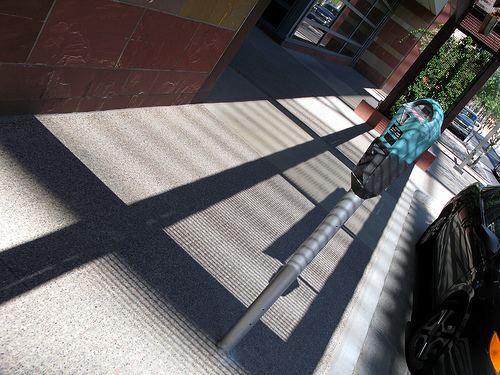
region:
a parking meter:
[350, 90, 450, 200]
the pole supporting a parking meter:
[217, 189, 362, 357]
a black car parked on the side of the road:
[411, 166, 497, 373]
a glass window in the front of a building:
[281, 0, 409, 60]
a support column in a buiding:
[440, 55, 497, 133]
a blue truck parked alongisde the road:
[451, 102, 481, 139]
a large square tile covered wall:
[0, 1, 259, 115]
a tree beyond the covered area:
[402, 43, 483, 119]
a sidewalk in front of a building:
[1, 102, 382, 373]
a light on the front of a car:
[486, 329, 498, 370]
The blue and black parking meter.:
[355, 84, 440, 209]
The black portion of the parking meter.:
[354, 143, 400, 196]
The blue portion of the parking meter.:
[379, 97, 446, 152]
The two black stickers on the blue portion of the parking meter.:
[389, 122, 407, 144]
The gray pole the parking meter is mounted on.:
[229, 187, 365, 334]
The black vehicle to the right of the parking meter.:
[412, 154, 497, 374]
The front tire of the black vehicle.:
[405, 301, 468, 357]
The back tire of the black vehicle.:
[414, 200, 449, 245]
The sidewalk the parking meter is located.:
[43, 137, 371, 361]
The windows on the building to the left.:
[286, 2, 408, 59]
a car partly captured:
[405, 168, 499, 373]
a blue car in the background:
[448, 92, 483, 146]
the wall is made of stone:
[1, 2, 253, 104]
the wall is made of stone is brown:
[30, 0, 141, 66]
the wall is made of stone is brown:
[122, 14, 233, 69]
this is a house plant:
[383, 22, 498, 126]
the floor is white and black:
[3, 84, 498, 371]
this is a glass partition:
[281, 1, 388, 56]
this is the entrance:
[203, 0, 435, 98]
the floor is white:
[40, 95, 300, 203]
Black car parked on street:
[414, 171, 499, 373]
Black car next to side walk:
[404, 181, 499, 367]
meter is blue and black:
[344, 73, 443, 216]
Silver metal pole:
[222, 177, 357, 369]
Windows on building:
[287, 5, 389, 72]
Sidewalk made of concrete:
[3, 71, 388, 366]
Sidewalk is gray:
[6, 55, 393, 372]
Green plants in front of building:
[375, 33, 492, 153]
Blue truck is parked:
[447, 98, 477, 143]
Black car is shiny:
[404, 181, 497, 371]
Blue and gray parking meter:
[350, 61, 448, 238]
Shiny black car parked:
[406, 181, 498, 369]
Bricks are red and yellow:
[2, 2, 256, 110]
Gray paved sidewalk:
[1, 79, 416, 374]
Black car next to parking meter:
[214, 96, 499, 374]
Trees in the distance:
[385, 39, 497, 157]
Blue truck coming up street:
[447, 101, 478, 149]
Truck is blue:
[453, 96, 480, 147]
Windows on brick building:
[276, 0, 436, 89]